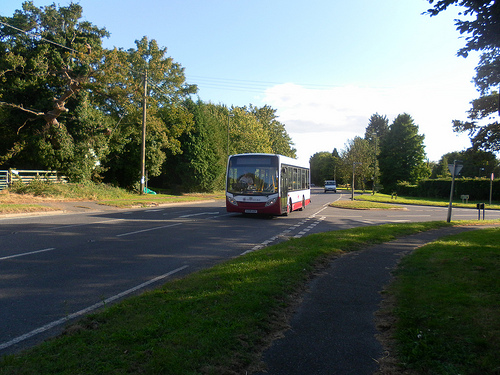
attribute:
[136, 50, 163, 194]
pole — brown, wooden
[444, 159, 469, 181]
sign — triangle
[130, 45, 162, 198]
post — wooden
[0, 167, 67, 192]
fence — grey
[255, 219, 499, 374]
sidewalk — black, concrete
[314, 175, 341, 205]
vehicle — white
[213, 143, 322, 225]
bus — red, white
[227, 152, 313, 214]
bus — red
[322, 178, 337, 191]
van — white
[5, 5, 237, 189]
trees — green